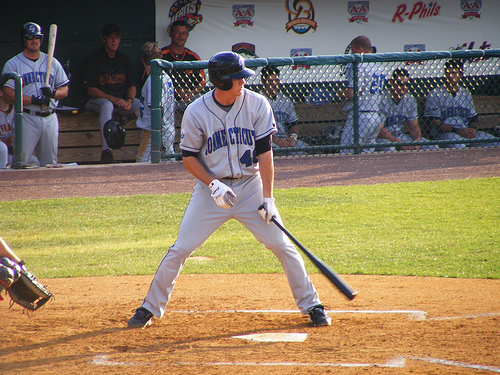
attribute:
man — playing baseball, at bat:
[127, 48, 332, 328]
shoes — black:
[126, 306, 332, 326]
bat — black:
[259, 201, 358, 301]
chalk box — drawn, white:
[91, 304, 429, 368]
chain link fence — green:
[149, 49, 500, 162]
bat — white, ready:
[44, 23, 58, 86]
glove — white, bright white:
[211, 177, 237, 208]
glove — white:
[258, 198, 280, 227]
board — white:
[155, 1, 500, 85]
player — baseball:
[425, 60, 494, 145]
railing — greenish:
[150, 47, 498, 160]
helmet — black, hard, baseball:
[21, 21, 42, 39]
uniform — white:
[428, 80, 499, 147]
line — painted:
[426, 312, 500, 324]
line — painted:
[417, 352, 499, 374]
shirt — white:
[176, 90, 277, 174]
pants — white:
[141, 176, 322, 320]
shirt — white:
[1, 48, 70, 111]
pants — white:
[10, 108, 58, 168]